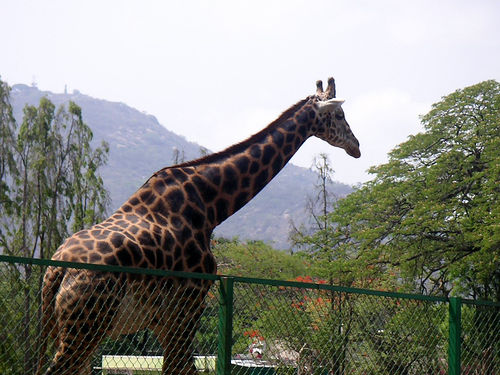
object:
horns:
[324, 77, 337, 95]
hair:
[158, 92, 313, 174]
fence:
[0, 253, 500, 372]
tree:
[294, 262, 378, 375]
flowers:
[296, 280, 327, 299]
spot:
[162, 182, 188, 216]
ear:
[317, 98, 347, 112]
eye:
[335, 112, 346, 121]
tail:
[21, 260, 69, 374]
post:
[212, 275, 237, 374]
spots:
[124, 212, 141, 225]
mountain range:
[0, 83, 214, 214]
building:
[224, 329, 305, 372]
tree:
[287, 150, 356, 373]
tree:
[13, 92, 113, 375]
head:
[310, 74, 364, 159]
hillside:
[0, 83, 197, 221]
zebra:
[32, 75, 363, 374]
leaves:
[257, 252, 281, 272]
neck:
[148, 95, 319, 234]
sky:
[0, 0, 497, 186]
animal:
[44, 74, 366, 374]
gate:
[0, 254, 458, 374]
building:
[97, 346, 280, 373]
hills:
[0, 77, 376, 255]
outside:
[0, 0, 499, 373]